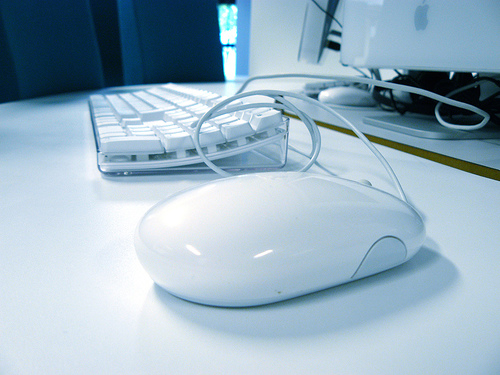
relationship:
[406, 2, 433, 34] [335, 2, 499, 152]
icon on computer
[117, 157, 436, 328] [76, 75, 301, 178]
mouse near keyboard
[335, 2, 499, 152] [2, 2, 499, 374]
computer in room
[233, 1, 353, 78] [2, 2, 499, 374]
wall in room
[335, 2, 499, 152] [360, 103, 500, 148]
computer on stand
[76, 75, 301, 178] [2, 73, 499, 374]
keyboard on desk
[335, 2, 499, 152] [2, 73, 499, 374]
computer on table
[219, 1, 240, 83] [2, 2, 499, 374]
window in room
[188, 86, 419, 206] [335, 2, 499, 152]
wire for computer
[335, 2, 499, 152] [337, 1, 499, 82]
computer has monitor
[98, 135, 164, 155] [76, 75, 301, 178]
key on keyboard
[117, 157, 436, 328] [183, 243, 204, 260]
mouse has reflection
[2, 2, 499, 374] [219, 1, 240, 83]
room has window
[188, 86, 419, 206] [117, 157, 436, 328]
wire on mouse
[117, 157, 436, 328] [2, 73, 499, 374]
mouse on table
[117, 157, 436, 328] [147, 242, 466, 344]
mouse has shadow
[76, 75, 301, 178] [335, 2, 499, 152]
keyboard for computer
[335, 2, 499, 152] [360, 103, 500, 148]
computer has stand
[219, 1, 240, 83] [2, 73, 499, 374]
window behind table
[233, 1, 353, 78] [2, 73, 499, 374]
wall behind table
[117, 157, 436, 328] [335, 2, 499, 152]
mouse for computer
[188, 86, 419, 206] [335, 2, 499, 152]
wire to computer